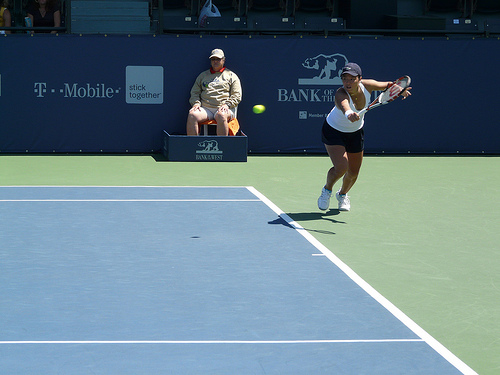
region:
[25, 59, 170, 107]
T Mobile is being advertised on the wall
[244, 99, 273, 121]
The tennis ball is in the air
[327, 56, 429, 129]
Player is swinging a tennis racket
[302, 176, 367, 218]
Player is wearing white shoes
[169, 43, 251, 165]
Man is sitting in judging box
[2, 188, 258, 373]
The court area is blue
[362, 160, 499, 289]
The out-of-bounds area is green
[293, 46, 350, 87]
Image of a bear on the wall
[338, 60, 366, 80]
Woman is wearing a blue hat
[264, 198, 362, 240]
Woman's shadow on the ground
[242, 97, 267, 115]
a yellow tennis ball in the air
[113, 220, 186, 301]
a blue section of a tennis court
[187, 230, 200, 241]
the shadow of the tennis ball reflecting on the court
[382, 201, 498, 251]
a section of green court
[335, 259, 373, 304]
a white line dividing blue from green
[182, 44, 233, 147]
a man sitting in a chair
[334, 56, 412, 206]
a woman playing tennis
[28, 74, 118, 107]
the Tmobile logo on a banner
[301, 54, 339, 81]
an image of a bear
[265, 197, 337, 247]
a tennis player's shadow on the court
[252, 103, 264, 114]
green tennis ball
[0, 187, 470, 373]
blue and white court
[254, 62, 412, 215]
lady hitting green tennis ball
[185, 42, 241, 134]
man sitting watching game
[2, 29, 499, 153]
blue wall in background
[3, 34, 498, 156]
blue wall has two white ads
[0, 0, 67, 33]
two fans sitting in stands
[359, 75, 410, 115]
red white and black racket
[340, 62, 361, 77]
navy blue tennis hat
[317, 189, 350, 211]
white and tied gym shoes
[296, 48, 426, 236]
A woman is playing tennis.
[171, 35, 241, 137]
The man is sitting down.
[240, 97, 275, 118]
A tennis ball in the air.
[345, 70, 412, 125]
The woman is holding a racket.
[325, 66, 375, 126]
The woman is wearing a white top.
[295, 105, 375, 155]
The woman is wearing black shorts.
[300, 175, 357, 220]
The woman is wearing white tennis shoes.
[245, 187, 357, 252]
A shadow of the woman on the ground.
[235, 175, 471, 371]
A white stripe painted on the tennis court.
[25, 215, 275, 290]
This part of the ground is blue.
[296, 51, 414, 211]
person playing a game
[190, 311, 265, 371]
white line in court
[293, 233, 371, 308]
out of bound line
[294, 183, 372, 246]
feet of the lady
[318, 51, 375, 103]
hat on lady's head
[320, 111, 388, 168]
shorts on the lady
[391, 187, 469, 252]
green court outside the boundary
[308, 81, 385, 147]
white shirt on lady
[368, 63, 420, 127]
tennis racket in lady's hand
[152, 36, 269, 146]
man sitting on chair